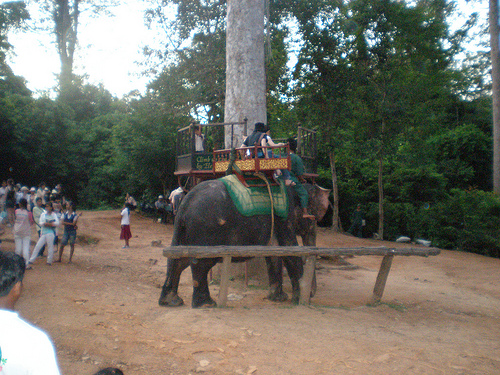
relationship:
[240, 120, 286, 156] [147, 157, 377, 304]
people riding elephant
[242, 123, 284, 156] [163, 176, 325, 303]
people riding elephant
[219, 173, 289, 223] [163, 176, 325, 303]
pad on elephant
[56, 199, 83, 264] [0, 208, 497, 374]
person standing in brown dirt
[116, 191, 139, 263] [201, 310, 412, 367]
person standing in dirt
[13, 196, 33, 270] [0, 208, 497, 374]
person standing in brown dirt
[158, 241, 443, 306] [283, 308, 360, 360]
post in ground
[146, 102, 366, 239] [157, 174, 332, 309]
people riding elephant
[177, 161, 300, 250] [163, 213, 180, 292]
elephant has tail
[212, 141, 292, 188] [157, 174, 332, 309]
saddle on top of elephant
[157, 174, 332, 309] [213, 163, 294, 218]
elephant has blanket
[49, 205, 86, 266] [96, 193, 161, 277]
girl wearing shirt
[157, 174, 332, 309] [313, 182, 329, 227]
elephant has ear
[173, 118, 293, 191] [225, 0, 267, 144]
deck around trunk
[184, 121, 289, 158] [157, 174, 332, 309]
they on elephant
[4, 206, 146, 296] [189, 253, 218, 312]
pink areas on hind leg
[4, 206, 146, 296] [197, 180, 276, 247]
pink areas on body